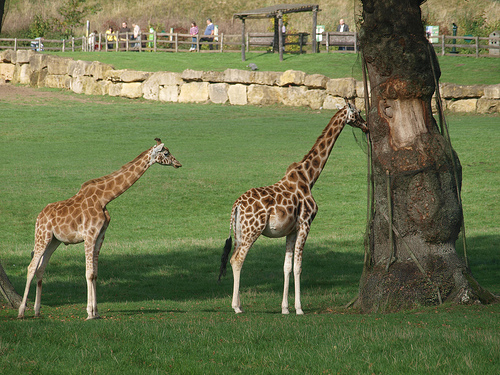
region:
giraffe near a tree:
[220, 95, 375, 315]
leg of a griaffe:
[286, 208, 307, 319]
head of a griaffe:
[330, 88, 373, 129]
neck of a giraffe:
[287, 108, 343, 179]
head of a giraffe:
[127, 130, 179, 165]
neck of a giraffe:
[75, 155, 145, 195]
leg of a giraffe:
[70, 217, 105, 323]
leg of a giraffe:
[230, 236, 252, 314]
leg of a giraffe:
[17, 230, 47, 318]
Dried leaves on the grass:
[57, 304, 134, 330]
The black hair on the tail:
[210, 230, 237, 282]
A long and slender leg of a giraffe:
[72, 244, 112, 320]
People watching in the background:
[78, 14, 226, 54]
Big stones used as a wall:
[113, 65, 325, 110]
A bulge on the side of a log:
[398, 170, 478, 244]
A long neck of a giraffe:
[298, 125, 346, 180]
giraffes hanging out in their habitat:
[13, 87, 373, 335]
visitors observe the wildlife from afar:
[21, 12, 473, 57]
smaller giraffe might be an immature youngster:
[11, 130, 186, 330]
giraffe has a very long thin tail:
[211, 186, 243, 286]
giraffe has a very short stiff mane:
[281, 100, 346, 180]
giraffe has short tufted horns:
[145, 132, 186, 172]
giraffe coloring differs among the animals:
[13, 90, 375, 325]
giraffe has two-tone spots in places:
[250, 148, 322, 220]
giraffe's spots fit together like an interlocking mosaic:
[236, 175, 317, 245]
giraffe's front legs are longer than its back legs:
[11, 203, 123, 323]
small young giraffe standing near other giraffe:
[15, 136, 186, 324]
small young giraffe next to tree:
[213, 94, 373, 316]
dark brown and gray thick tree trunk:
[326, 0, 497, 317]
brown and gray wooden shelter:
[228, 0, 321, 61]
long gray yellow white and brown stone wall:
[0, 47, 498, 114]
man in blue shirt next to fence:
[196, 17, 218, 53]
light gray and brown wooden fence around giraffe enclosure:
[1, 29, 498, 61]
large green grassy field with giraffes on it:
[1, 78, 498, 373]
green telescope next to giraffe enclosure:
[447, 20, 460, 55]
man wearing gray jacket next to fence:
[334, 16, 351, 52]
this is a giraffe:
[10, 134, 183, 326]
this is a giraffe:
[215, 101, 370, 317]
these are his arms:
[81, 231, 107, 323]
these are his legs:
[17, 243, 49, 317]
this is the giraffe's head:
[147, 130, 181, 171]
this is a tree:
[327, 0, 499, 312]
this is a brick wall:
[1, 45, 497, 112]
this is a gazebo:
[234, 1, 325, 63]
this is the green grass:
[1, 102, 496, 373]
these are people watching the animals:
[84, 19, 221, 52]